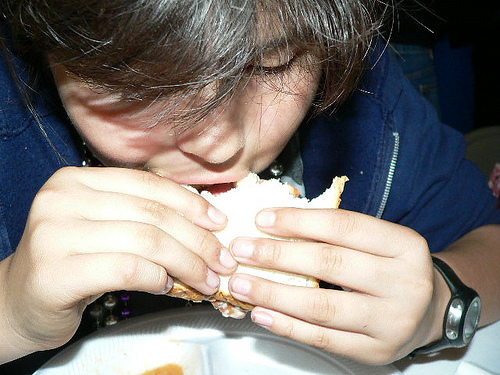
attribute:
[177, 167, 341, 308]
bread — white, half-eaten, partially eaten, here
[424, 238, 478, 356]
watch — here, black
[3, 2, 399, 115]
hair — black, brown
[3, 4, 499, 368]
person — here, light skinned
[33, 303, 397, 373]
plate — white, circular, styrofoam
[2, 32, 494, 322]
sweater — blue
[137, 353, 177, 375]
stain — brown, from bread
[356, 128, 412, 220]
zipper — silver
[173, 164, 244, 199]
mouth — open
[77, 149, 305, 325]
beads — silver, purple